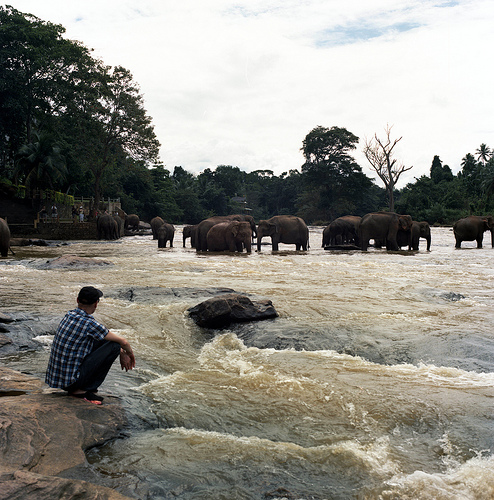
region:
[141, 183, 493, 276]
herd of elephants in water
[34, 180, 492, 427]
man watching elephants in water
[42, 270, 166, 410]
man squatting on rock in river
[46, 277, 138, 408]
man popping squat on rocky river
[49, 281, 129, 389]
man in blue plaid shirt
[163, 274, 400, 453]
rocks and rapids of river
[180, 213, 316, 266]
elephants drinking water in river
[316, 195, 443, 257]
group of elephants huddled together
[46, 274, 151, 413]
brunette man wearing blue shirt and black pants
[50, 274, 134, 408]
man in blue shirt and black pants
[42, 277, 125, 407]
man sitting on large rock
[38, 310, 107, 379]
black and white plaid shirt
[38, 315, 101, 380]
black and white flannel shirt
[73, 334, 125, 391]
dark blue jeans on man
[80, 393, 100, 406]
black and orange shoes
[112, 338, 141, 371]
hands of man crossed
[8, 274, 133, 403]
man squatting down on ground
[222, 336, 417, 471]
water flowing in river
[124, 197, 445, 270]
herd of elephants together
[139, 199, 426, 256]
herd of elephants in river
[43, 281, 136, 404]
man sitting by river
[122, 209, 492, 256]
herd of large elephants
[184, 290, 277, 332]
large boulder in middle of river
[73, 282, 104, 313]
black cap on head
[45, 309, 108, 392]
plaid short sleeve shirt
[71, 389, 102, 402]
black rubber shoes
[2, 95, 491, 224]
green leaves on trees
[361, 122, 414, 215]
dead tree with no leaves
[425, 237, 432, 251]
long grey elephant trunk inwater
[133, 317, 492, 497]
rapids on river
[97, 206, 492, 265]
Heard of elephants in the water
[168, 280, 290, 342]
Large rock in the middle of a raging river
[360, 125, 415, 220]
Dying tree in the middle of a bunch of healthy trees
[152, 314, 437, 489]
Brown river water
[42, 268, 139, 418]
Man crouched on a rock watching the elephants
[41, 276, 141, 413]
Man in a hat and plaid shirt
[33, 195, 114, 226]
People on a ledge watching the elephants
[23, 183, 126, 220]
Fence on some type of animal preserve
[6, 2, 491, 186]
Bright white sky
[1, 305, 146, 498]
Rocky river bank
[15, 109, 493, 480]
A person sitting near the river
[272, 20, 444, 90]
A blue color sky with clouds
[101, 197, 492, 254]
Lot of elephants standing in the river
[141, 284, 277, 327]
Stone near the water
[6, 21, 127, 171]
Trees with green leaves and branches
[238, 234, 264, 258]
Trunk of the elephant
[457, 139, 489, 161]
Coconut tree near the river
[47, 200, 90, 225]
Peoples standing near the tree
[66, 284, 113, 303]
A person wearing hat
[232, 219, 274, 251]
Head of the elephant